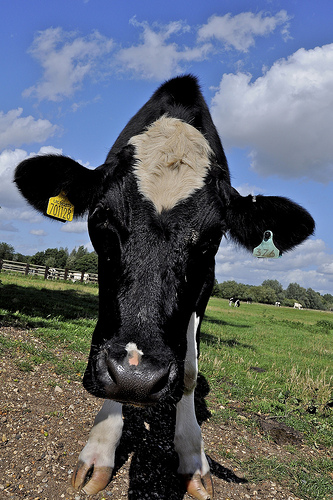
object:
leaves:
[261, 285, 272, 298]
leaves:
[45, 241, 68, 263]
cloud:
[211, 40, 331, 180]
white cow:
[294, 302, 303, 309]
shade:
[0, 280, 100, 331]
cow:
[15, 76, 317, 500]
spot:
[129, 115, 211, 213]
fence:
[1, 259, 100, 285]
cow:
[46, 268, 56, 279]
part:
[247, 70, 268, 90]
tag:
[45, 191, 74, 221]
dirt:
[0, 303, 97, 499]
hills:
[3, 284, 331, 499]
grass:
[1, 270, 333, 497]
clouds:
[195, 4, 293, 53]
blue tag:
[252, 229, 280, 261]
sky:
[0, 0, 332, 295]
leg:
[82, 397, 124, 465]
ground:
[0, 272, 333, 497]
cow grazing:
[228, 297, 240, 308]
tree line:
[211, 278, 331, 311]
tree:
[261, 277, 281, 303]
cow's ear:
[15, 152, 96, 225]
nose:
[97, 340, 173, 401]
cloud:
[16, 23, 119, 110]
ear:
[230, 195, 314, 259]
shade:
[111, 370, 249, 500]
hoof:
[179, 467, 215, 500]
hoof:
[68, 451, 119, 499]